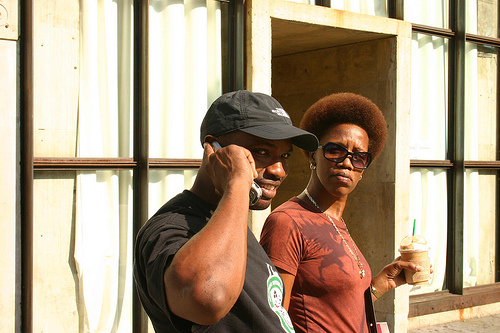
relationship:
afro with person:
[258, 89, 432, 333] [131, 91, 299, 333]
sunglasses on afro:
[318, 142, 371, 168] [258, 89, 432, 333]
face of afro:
[316, 120, 374, 191] [258, 89, 432, 333]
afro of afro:
[296, 84, 388, 167] [258, 89, 432, 333]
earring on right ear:
[310, 161, 320, 173] [305, 144, 319, 170]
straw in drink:
[409, 217, 423, 243] [399, 242, 430, 286]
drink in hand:
[399, 242, 430, 286] [385, 257, 436, 297]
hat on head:
[199, 92, 318, 152] [198, 132, 295, 204]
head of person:
[198, 132, 295, 204] [131, 91, 299, 333]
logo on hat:
[266, 107, 295, 120] [199, 92, 318, 152]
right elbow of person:
[161, 257, 240, 327] [131, 91, 299, 333]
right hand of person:
[204, 143, 260, 190] [131, 91, 299, 333]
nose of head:
[268, 158, 290, 182] [198, 132, 295, 204]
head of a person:
[198, 132, 295, 204] [131, 91, 299, 333]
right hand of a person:
[204, 143, 260, 190] [131, 91, 299, 333]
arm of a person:
[148, 176, 255, 324] [131, 91, 299, 333]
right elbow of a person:
[161, 257, 240, 327] [131, 91, 299, 333]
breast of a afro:
[302, 239, 358, 297] [258, 89, 432, 333]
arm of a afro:
[261, 216, 306, 306] [258, 89, 432, 333]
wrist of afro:
[370, 269, 391, 298] [258, 89, 432, 333]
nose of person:
[268, 158, 290, 182] [131, 91, 299, 333]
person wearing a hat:
[131, 91, 299, 333] [199, 92, 318, 152]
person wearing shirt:
[131, 91, 299, 333] [124, 194, 297, 333]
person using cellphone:
[131, 91, 299, 333] [209, 152, 265, 206]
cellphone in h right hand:
[209, 152, 265, 206] [204, 143, 260, 190]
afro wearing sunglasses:
[258, 89, 432, 333] [318, 142, 371, 168]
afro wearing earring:
[258, 89, 432, 333] [310, 161, 320, 173]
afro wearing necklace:
[258, 89, 432, 333] [305, 188, 368, 280]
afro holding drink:
[258, 89, 432, 333] [399, 242, 430, 286]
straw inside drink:
[409, 217, 423, 243] [399, 242, 430, 286]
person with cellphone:
[131, 91, 299, 333] [209, 152, 265, 206]